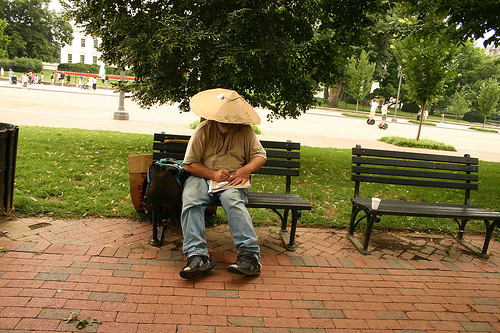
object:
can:
[2, 120, 19, 216]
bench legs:
[346, 207, 359, 232]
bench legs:
[360, 212, 375, 251]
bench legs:
[481, 220, 494, 255]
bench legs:
[456, 220, 466, 235]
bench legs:
[284, 210, 300, 249]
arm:
[183, 130, 213, 180]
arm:
[245, 130, 266, 175]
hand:
[223, 167, 251, 187]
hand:
[214, 168, 229, 180]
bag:
[137, 158, 186, 216]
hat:
[187, 87, 262, 127]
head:
[215, 121, 233, 134]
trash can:
[0, 121, 20, 222]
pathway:
[0, 215, 499, 333]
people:
[88, 75, 97, 93]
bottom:
[112, 108, 130, 120]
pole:
[117, 68, 125, 111]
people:
[378, 102, 391, 125]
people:
[367, 97, 378, 123]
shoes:
[178, 254, 217, 281]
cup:
[370, 195, 380, 212]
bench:
[343, 143, 497, 255]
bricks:
[307, 307, 350, 320]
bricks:
[171, 303, 209, 315]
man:
[177, 89, 267, 286]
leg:
[220, 188, 266, 255]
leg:
[179, 176, 209, 255]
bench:
[145, 131, 312, 253]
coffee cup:
[369, 198, 385, 208]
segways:
[377, 121, 388, 129]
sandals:
[226, 249, 261, 277]